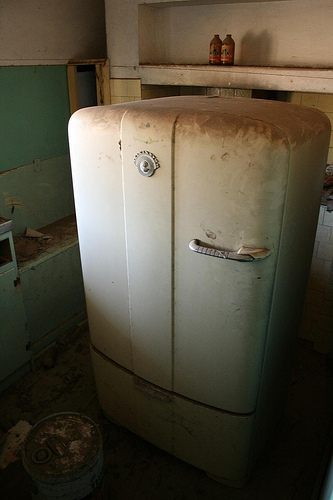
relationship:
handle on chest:
[187, 238, 272, 261] [66, 94, 333, 491]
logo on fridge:
[128, 150, 160, 179] [84, 73, 294, 298]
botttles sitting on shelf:
[204, 28, 241, 67] [136, 62, 330, 95]